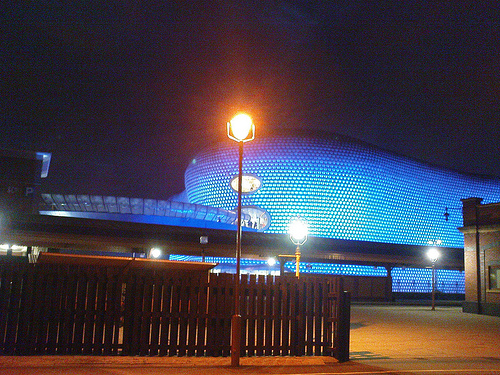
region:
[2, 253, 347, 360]
wooden fence in a lot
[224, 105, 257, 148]
light over a fence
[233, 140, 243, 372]
light post near a fence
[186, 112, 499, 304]
large blue lit building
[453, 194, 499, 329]
a brick building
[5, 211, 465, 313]
covered walkway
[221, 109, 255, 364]
Small orange street lamp in front of a fence.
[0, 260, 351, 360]
Short dark brown wooden fence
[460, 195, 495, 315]
Corner of a red brick and stone building.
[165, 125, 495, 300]
Non cubiod blue building with honeycomb patterns in its brickwork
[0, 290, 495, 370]
Illuminated white colored smooth pavement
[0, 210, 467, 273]
Breezeway in between blue building and pavement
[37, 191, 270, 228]
Blue glass hallway for foot traffic between buildings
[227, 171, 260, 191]
Large oval shaped window in blue building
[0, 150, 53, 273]
Cement and brick building with a "P" sign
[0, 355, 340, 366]
Slopped curb in front of a fence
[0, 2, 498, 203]
darkness of night sky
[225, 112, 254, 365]
glowing light on pole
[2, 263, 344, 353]
wood boars of fence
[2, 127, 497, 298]
glowing exterior of modern structure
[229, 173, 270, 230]
oval windows on structure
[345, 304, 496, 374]
light reflection on ground surface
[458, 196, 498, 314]
corner of brick building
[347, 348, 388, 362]
shadow of fence on ground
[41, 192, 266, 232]
glass cover over walkway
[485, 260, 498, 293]
window on brick building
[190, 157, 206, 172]
bright light on building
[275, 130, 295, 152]
bright light on building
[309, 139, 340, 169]
bright light on building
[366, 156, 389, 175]
bright light on building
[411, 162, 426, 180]
bright light on building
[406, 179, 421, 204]
bright light on building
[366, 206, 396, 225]
bright light on building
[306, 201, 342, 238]
bright light on building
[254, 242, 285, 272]
bright light on building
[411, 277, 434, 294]
bright light on building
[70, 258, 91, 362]
wood pole on fence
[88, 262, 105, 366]
wood pole on fence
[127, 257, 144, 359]
wood pole on fence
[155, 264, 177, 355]
wood pole on fence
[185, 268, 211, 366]
wood pole on fence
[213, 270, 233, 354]
wood pole on fence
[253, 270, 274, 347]
wood pole on fence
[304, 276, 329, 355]
wood pole on fence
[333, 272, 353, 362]
wood pole on fence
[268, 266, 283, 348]
wood pole on fence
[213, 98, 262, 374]
Light on a pole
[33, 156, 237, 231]
glass stage in blue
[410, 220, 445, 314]
light pole on the sidewalk